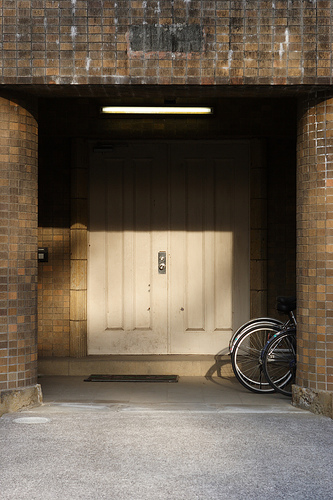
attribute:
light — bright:
[93, 100, 213, 117]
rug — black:
[84, 371, 177, 383]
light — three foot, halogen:
[102, 108, 210, 115]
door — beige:
[75, 143, 262, 378]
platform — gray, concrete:
[47, 380, 238, 444]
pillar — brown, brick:
[293, 90, 332, 418]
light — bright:
[101, 103, 212, 115]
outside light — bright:
[98, 103, 213, 116]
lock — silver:
[158, 254, 166, 263]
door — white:
[80, 134, 262, 366]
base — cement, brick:
[0, 379, 45, 415]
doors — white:
[88, 97, 329, 409]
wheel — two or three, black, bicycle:
[263, 327, 299, 394]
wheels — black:
[226, 312, 294, 395]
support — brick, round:
[1, 91, 45, 413]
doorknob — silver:
[152, 263, 171, 276]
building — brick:
[122, 10, 289, 79]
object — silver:
[98, 120, 177, 131]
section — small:
[89, 157, 125, 235]